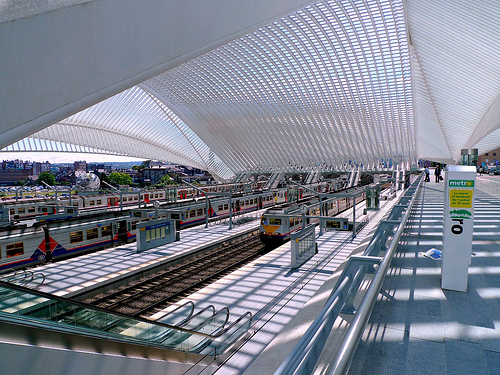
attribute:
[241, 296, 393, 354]
scene — outdoors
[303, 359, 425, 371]
scene — outdoors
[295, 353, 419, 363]
scene — outdoors